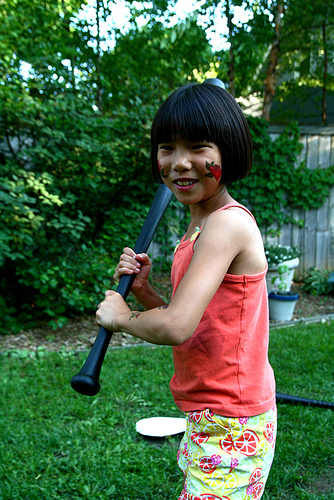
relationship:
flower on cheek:
[202, 158, 223, 179] [193, 148, 224, 191]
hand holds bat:
[87, 286, 136, 336] [31, 135, 178, 408]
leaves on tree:
[3, 1, 327, 306] [24, 11, 134, 263]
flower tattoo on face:
[204, 158, 223, 180] [147, 137, 225, 202]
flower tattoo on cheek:
[158, 160, 169, 179] [156, 155, 171, 178]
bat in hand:
[50, 89, 181, 369] [94, 288, 129, 329]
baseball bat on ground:
[275, 389, 333, 409] [0, 319, 333, 498]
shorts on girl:
[167, 400, 286, 498] [84, 71, 292, 498]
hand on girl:
[110, 244, 152, 288] [92, 81, 279, 498]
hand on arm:
[110, 244, 152, 288] [139, 282, 165, 310]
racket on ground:
[128, 407, 200, 445] [7, 291, 331, 496]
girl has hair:
[92, 81, 279, 498] [149, 81, 252, 184]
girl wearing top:
[92, 81, 279, 498] [169, 203, 280, 411]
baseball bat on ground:
[276, 392, 334, 409] [7, 291, 331, 496]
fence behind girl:
[151, 131, 332, 284] [77, 59, 333, 491]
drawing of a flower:
[202, 161, 223, 182] [210, 164, 223, 182]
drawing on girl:
[202, 161, 223, 182] [92, 81, 279, 498]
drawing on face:
[202, 161, 223, 182] [157, 141, 223, 204]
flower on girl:
[210, 164, 223, 182] [92, 81, 279, 498]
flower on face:
[210, 164, 223, 182] [157, 141, 223, 204]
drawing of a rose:
[128, 313, 138, 322] [126, 309, 139, 322]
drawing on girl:
[128, 313, 138, 322] [146, 102, 291, 319]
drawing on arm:
[128, 313, 138, 322] [121, 307, 184, 343]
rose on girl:
[126, 309, 139, 322] [146, 102, 291, 319]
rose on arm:
[126, 309, 139, 322] [121, 307, 184, 343]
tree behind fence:
[254, 0, 287, 141] [151, 131, 332, 284]